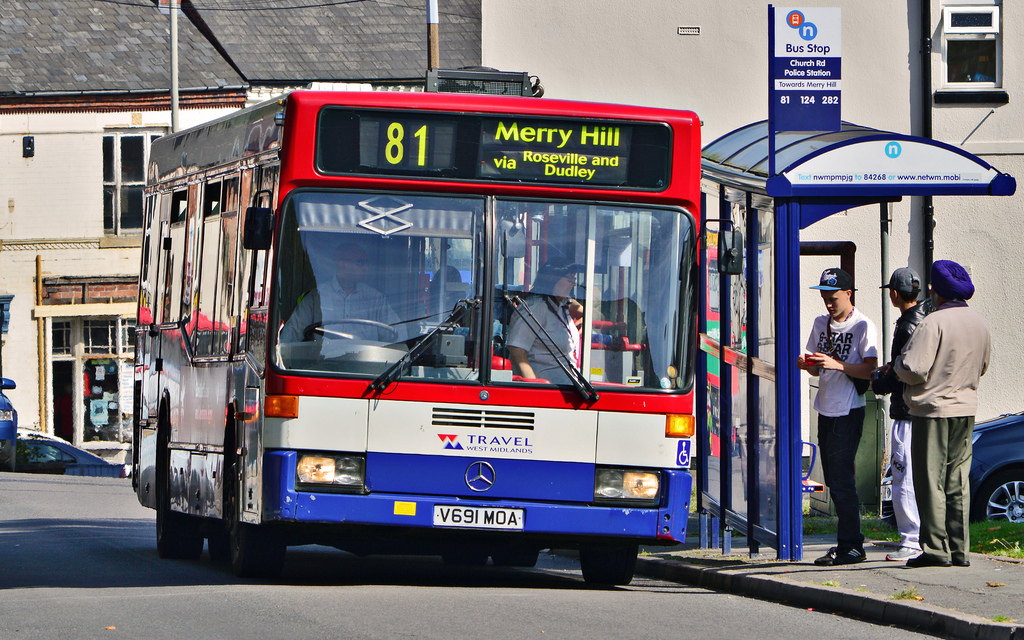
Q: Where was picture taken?
A: At the bus stop.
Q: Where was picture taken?
A: At a bus stop.